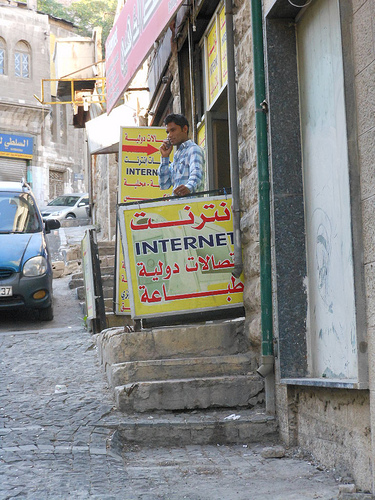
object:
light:
[33, 289, 46, 299]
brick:
[54, 445, 72, 454]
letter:
[170, 237, 183, 251]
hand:
[172, 183, 190, 197]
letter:
[183, 235, 197, 250]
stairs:
[106, 321, 246, 359]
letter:
[141, 239, 158, 254]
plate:
[0, 285, 13, 297]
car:
[0, 178, 62, 323]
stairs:
[98, 246, 115, 254]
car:
[40, 192, 90, 219]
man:
[158, 112, 206, 198]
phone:
[165, 137, 171, 148]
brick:
[260, 445, 286, 458]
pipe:
[250, 0, 278, 414]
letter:
[227, 231, 235, 245]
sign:
[117, 193, 247, 321]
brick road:
[0, 276, 343, 498]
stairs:
[114, 412, 280, 447]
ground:
[0, 313, 374, 498]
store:
[103, 0, 371, 500]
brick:
[73, 425, 96, 435]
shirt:
[157, 139, 207, 198]